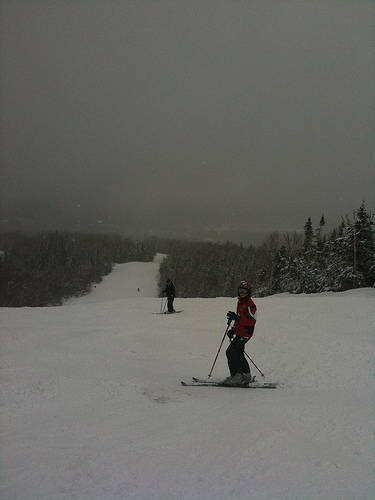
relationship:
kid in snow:
[218, 263, 268, 381] [68, 332, 137, 419]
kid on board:
[218, 263, 268, 381] [195, 375, 237, 397]